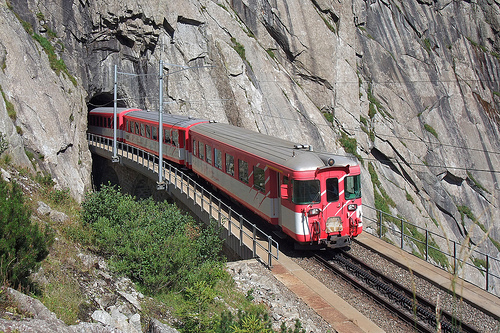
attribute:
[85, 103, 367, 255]
train — coming out, red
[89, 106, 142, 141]
train car — three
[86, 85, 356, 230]
train — red, silver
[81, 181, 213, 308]
bushes — green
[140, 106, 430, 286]
train — red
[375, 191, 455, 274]
plants — green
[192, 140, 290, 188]
windows — reflective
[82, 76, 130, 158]
train tunnel — train tunnel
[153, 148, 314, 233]
stripe — white